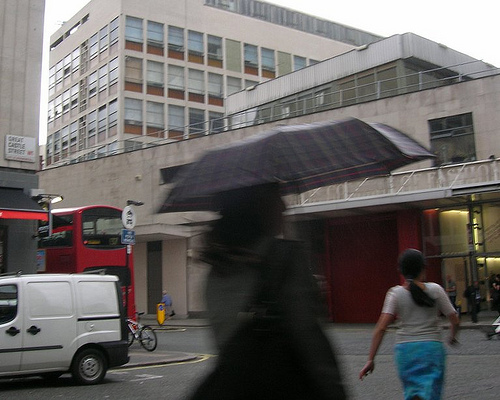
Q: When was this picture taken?
A: During the day.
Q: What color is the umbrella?
A: Black.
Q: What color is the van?
A: White.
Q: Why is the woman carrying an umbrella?
A: It's raining.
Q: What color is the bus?
A: Red.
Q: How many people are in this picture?
A: Two.